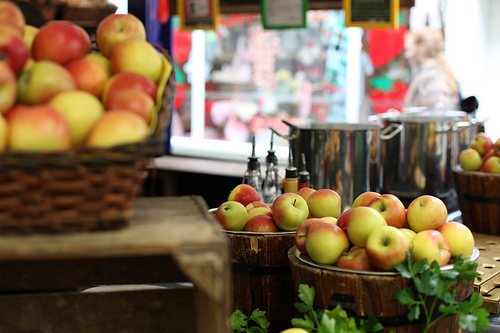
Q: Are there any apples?
A: Yes, there is an apple.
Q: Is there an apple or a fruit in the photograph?
A: Yes, there is an apple.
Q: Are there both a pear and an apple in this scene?
A: No, there is an apple but no pears.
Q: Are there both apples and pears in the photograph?
A: No, there is an apple but no pears.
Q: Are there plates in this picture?
A: No, there are no plates.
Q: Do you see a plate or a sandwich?
A: No, there are no plates or sandwiches.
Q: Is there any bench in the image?
A: Yes, there is a bench.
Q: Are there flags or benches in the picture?
A: Yes, there is a bench.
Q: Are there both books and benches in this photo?
A: No, there is a bench but no books.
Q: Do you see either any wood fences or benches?
A: Yes, there is a wood bench.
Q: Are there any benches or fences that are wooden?
A: Yes, the bench is wooden.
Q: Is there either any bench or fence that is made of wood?
A: Yes, the bench is made of wood.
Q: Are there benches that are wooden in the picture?
A: Yes, there is a wood bench.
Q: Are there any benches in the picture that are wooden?
A: Yes, there is a bench that is wooden.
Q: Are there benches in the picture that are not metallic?
A: Yes, there is a wooden bench.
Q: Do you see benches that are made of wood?
A: Yes, there is a bench that is made of wood.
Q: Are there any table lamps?
A: No, there are no table lamps.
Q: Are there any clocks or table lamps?
A: No, there are no table lamps or clocks.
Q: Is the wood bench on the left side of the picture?
A: Yes, the bench is on the left of the image.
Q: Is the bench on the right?
A: No, the bench is on the left of the image.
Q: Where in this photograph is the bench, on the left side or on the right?
A: The bench is on the left of the image.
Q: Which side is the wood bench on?
A: The bench is on the left of the image.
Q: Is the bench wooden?
A: Yes, the bench is wooden.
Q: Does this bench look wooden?
A: Yes, the bench is wooden.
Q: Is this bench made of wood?
A: Yes, the bench is made of wood.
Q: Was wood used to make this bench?
A: Yes, the bench is made of wood.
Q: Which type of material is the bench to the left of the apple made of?
A: The bench is made of wood.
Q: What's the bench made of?
A: The bench is made of wood.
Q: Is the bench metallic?
A: No, the bench is wooden.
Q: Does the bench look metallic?
A: No, the bench is wooden.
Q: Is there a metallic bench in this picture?
A: No, there is a bench but it is wooden.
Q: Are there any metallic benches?
A: No, there is a bench but it is wooden.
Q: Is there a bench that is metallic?
A: No, there is a bench but it is wooden.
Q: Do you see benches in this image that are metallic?
A: No, there is a bench but it is wooden.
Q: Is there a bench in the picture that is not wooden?
A: No, there is a bench but it is wooden.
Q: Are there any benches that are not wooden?
A: No, there is a bench but it is wooden.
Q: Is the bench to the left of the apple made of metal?
A: No, the bench is made of wood.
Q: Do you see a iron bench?
A: No, there is a bench but it is made of wood.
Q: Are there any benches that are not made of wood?
A: No, there is a bench but it is made of wood.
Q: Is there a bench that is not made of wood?
A: No, there is a bench but it is made of wood.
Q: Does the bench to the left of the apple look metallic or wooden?
A: The bench is wooden.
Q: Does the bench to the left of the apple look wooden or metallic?
A: The bench is wooden.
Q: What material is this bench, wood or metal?
A: The bench is made of wood.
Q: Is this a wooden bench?
A: Yes, this is a wooden bench.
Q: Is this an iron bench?
A: No, this is a wooden bench.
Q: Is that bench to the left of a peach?
A: No, the bench is to the left of the apple.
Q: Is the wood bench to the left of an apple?
A: Yes, the bench is to the left of an apple.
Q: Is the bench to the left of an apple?
A: Yes, the bench is to the left of an apple.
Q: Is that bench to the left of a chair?
A: No, the bench is to the left of an apple.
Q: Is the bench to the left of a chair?
A: No, the bench is to the left of an apple.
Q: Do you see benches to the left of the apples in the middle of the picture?
A: Yes, there is a bench to the left of the apples.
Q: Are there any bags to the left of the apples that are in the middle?
A: No, there is a bench to the left of the apples.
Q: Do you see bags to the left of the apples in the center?
A: No, there is a bench to the left of the apples.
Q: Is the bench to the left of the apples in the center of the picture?
A: Yes, the bench is to the left of the apples.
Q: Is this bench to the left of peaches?
A: No, the bench is to the left of the apples.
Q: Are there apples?
A: Yes, there is an apple.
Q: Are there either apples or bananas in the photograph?
A: Yes, there is an apple.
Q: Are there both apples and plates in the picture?
A: No, there is an apple but no plates.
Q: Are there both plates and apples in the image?
A: No, there is an apple but no plates.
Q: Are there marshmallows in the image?
A: No, there are no marshmallows.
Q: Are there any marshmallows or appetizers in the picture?
A: No, there are no marshmallows or appetizers.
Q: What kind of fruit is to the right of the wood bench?
A: The fruit is an apple.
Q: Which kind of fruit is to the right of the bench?
A: The fruit is an apple.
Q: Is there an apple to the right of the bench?
A: Yes, there is an apple to the right of the bench.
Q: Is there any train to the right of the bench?
A: No, there is an apple to the right of the bench.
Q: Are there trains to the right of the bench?
A: No, there is an apple to the right of the bench.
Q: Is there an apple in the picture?
A: Yes, there is an apple.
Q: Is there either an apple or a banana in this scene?
A: Yes, there is an apple.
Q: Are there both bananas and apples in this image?
A: No, there is an apple but no bananas.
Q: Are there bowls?
A: No, there are no bowls.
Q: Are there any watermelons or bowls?
A: No, there are no bowls or watermelons.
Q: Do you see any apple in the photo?
A: Yes, there is an apple.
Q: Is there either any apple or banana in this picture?
A: Yes, there is an apple.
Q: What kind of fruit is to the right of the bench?
A: The fruit is an apple.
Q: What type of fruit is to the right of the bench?
A: The fruit is an apple.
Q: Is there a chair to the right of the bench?
A: No, there is an apple to the right of the bench.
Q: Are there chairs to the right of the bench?
A: No, there is an apple to the right of the bench.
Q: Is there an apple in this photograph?
A: Yes, there is an apple.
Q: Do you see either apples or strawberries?
A: Yes, there is an apple.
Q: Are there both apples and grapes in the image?
A: No, there is an apple but no grapes.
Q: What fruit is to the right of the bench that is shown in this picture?
A: The fruit is an apple.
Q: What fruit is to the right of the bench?
A: The fruit is an apple.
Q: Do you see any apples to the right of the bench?
A: Yes, there is an apple to the right of the bench.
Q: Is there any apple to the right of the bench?
A: Yes, there is an apple to the right of the bench.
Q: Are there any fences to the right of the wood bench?
A: No, there is an apple to the right of the bench.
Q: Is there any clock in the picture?
A: No, there are no clocks.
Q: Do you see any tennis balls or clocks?
A: No, there are no clocks or tennis balls.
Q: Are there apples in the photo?
A: Yes, there is an apple.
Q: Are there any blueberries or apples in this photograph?
A: Yes, there is an apple.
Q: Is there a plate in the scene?
A: No, there are no plates.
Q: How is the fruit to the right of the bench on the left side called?
A: The fruit is an apple.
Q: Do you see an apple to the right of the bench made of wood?
A: Yes, there is an apple to the right of the bench.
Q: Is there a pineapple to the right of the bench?
A: No, there is an apple to the right of the bench.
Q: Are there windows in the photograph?
A: Yes, there is a window.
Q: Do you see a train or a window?
A: Yes, there is a window.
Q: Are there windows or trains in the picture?
A: Yes, there is a window.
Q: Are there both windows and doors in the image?
A: No, there is a window but no doors.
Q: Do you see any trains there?
A: No, there are no trains.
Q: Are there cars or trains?
A: No, there are no trains or cars.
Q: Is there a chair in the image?
A: No, there are no chairs.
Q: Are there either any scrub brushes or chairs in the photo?
A: No, there are no chairs or scrub brushes.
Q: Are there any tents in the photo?
A: No, there are no tents.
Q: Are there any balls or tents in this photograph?
A: No, there are no tents or balls.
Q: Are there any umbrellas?
A: No, there are no umbrellas.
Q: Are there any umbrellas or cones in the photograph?
A: No, there are no umbrellas or cones.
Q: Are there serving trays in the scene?
A: No, there are no serving trays.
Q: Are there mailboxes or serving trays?
A: No, there are no serving trays or mailboxes.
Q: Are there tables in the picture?
A: Yes, there is a table.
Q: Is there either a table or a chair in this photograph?
A: Yes, there is a table.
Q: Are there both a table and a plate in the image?
A: No, there is a table but no plates.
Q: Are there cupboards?
A: No, there are no cupboards.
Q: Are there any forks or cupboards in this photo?
A: No, there are no cupboards or forks.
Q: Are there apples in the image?
A: Yes, there are apples.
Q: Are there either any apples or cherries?
A: Yes, there are apples.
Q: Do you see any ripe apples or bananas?
A: Yes, there are ripe apples.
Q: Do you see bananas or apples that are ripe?
A: Yes, the apples are ripe.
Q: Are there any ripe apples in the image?
A: Yes, there are ripe apples.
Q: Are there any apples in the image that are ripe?
A: Yes, there are apples that are ripe.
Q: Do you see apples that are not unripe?
A: Yes, there are ripe apples.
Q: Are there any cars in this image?
A: No, there are no cars.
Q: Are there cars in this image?
A: No, there are no cars.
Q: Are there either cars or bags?
A: No, there are no cars or bags.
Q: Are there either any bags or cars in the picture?
A: No, there are no cars or bags.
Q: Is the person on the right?
A: Yes, the person is on the right of the image.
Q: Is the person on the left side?
A: No, the person is on the right of the image.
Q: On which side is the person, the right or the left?
A: The person is on the right of the image.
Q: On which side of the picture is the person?
A: The person is on the right of the image.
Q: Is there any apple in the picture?
A: Yes, there are apples.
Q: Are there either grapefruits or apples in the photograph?
A: Yes, there are apples.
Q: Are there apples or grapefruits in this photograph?
A: Yes, there are apples.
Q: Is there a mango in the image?
A: No, there are no mangoes.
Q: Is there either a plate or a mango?
A: No, there are no mangoes or plates.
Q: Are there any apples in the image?
A: Yes, there are apples.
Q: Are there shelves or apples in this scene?
A: Yes, there are apples.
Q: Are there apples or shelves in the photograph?
A: Yes, there are apples.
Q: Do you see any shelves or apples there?
A: Yes, there are apples.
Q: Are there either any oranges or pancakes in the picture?
A: No, there are no oranges or pancakes.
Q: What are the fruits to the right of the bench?
A: The fruits are apples.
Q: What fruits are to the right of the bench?
A: The fruits are apples.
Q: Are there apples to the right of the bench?
A: Yes, there are apples to the right of the bench.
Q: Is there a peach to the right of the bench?
A: No, there are apples to the right of the bench.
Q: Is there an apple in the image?
A: Yes, there is an apple.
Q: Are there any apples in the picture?
A: Yes, there is an apple.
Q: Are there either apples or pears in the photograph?
A: Yes, there is an apple.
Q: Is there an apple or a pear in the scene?
A: Yes, there is an apple.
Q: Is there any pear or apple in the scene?
A: Yes, there is an apple.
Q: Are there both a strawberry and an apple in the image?
A: No, there is an apple but no strawberries.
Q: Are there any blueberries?
A: No, there are no blueberries.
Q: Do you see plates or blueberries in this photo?
A: No, there are no blueberries or plates.